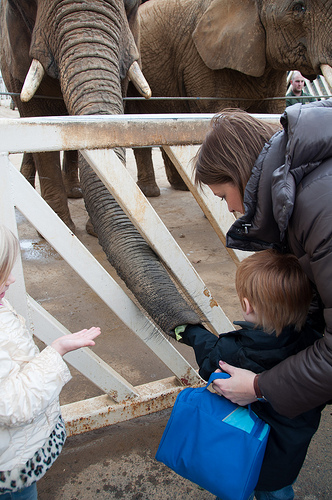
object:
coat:
[223, 103, 331, 412]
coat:
[176, 324, 322, 485]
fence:
[1, 113, 287, 431]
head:
[0, 229, 23, 305]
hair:
[0, 233, 18, 286]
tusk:
[18, 57, 44, 103]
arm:
[173, 254, 327, 499]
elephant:
[128, 4, 329, 199]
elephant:
[0, 0, 206, 335]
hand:
[211, 361, 255, 407]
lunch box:
[154, 370, 272, 497]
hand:
[53, 325, 102, 352]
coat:
[0, 297, 70, 494]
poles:
[4, 146, 243, 404]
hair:
[234, 249, 309, 336]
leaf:
[175, 323, 188, 341]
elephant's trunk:
[41, 9, 203, 339]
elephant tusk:
[125, 58, 152, 101]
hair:
[188, 107, 281, 216]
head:
[188, 105, 275, 219]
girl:
[0, 226, 101, 498]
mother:
[191, 105, 332, 406]